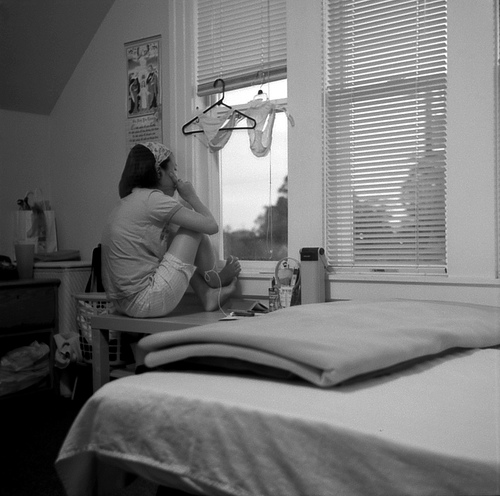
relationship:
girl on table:
[108, 136, 245, 321] [90, 311, 236, 345]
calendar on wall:
[119, 23, 164, 156] [55, 12, 169, 225]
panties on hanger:
[197, 108, 245, 148] [178, 78, 255, 136]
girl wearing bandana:
[108, 136, 245, 321] [136, 137, 177, 170]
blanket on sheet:
[134, 297, 498, 384] [90, 352, 498, 495]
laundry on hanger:
[197, 108, 245, 148] [178, 78, 255, 136]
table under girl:
[90, 311, 236, 345] [108, 136, 245, 321]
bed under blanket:
[90, 352, 498, 495] [134, 297, 498, 384]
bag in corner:
[4, 195, 68, 270] [14, 93, 89, 270]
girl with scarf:
[108, 136, 245, 321] [136, 137, 177, 170]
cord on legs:
[205, 249, 234, 316] [147, 222, 245, 319]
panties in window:
[197, 108, 245, 148] [189, 4, 294, 270]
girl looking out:
[108, 136, 245, 321] [195, 89, 308, 257]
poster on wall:
[117, 33, 182, 173] [55, 12, 169, 225]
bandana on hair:
[136, 137, 177, 170] [116, 139, 173, 197]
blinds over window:
[325, 6, 455, 280] [320, 7, 455, 271]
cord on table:
[205, 249, 234, 316] [90, 311, 236, 345]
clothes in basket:
[86, 299, 118, 355] [64, 293, 122, 361]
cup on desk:
[13, 240, 40, 281] [3, 275, 61, 375]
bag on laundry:
[4, 195, 68, 270] [36, 259, 95, 350]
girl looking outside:
[108, 136, 245, 321] [195, 89, 308, 257]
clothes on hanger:
[197, 108, 245, 148] [178, 78, 255, 136]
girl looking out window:
[108, 136, 245, 321] [189, 4, 294, 270]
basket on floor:
[64, 293, 122, 361] [1, 372, 117, 492]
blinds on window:
[325, 6, 455, 280] [320, 7, 455, 271]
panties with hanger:
[197, 108, 245, 148] [178, 78, 255, 136]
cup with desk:
[13, 240, 40, 281] [3, 275, 61, 375]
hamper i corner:
[20, 256, 115, 338] [14, 93, 89, 270]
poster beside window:
[117, 33, 182, 173] [189, 4, 294, 270]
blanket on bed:
[134, 297, 498, 384] [132, 287, 482, 487]